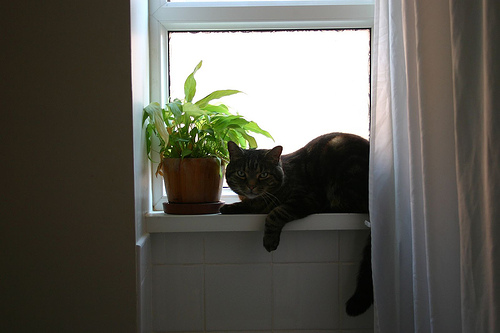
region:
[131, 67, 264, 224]
a potted plant on the windowsill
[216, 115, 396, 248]
cat next to the window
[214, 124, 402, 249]
cat on the windowsill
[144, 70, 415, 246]
cat next to the plant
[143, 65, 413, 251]
plant next to the cat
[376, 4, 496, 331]
white curtains for the window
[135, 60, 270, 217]
green plant in a brown pot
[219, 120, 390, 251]
cat on a white windowsill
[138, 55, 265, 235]
plant on a white windowsill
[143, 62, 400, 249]
plant and cat on a white window sill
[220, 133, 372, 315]
a cat sitting on the window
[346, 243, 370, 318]
the tail is hanging down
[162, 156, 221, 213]
a brown pot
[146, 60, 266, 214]
the potted house plant is green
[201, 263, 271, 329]
white square tile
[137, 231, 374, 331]
part of the wall is tiled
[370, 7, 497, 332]
a white curtain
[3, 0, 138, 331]
the wall is painted brown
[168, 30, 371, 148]
light shining through the window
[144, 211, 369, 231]
a white window sill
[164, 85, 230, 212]
plant in the window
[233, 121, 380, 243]
cat in the window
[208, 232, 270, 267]
tile on the wall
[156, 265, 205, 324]
tile on the wall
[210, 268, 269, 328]
tile on the wall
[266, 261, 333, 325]
tile on the wall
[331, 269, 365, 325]
tile on the wall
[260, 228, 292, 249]
paw of the cat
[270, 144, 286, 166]
ear of the cat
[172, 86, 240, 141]
green potted plant in window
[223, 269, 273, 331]
white tile on wall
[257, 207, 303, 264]
cat's paw hanging down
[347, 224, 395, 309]
cat's dark tail hanging down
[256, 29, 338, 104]
sunlight outside of window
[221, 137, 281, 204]
dark head of a cat in window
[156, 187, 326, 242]
white window sill under cat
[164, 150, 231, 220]
brown ceramic pot for plant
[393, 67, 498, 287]
white curtain in front of cat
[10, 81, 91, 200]
beige portion of wall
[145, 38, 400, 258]
a cat sitting on a windowsill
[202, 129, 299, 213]
the head of a gray cat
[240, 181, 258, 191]
the nose of a gray cat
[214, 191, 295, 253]
the paws of a gray cat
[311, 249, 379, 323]
the tail of a gray cat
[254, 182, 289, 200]
the whiskers of a gray cat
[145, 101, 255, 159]
the green leaves of a house plant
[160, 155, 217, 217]
a small brown plant pot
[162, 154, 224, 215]
saucer under pot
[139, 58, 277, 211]
green houseplant growing in pot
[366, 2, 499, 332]
long white cloth curtain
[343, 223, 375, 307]
tail below window sill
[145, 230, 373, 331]
white tiles under window sill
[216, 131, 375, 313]
cat sitting in front of window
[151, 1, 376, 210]
frosted window behind houseplant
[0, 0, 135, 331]
tan wall to the left of house plant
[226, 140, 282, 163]
the cat has pointy ears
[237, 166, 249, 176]
cat has an eye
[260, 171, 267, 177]
cat has an eye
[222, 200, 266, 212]
cat has a leg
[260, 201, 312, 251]
cat has a leg